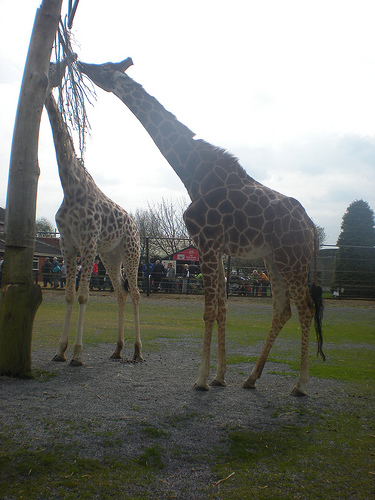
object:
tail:
[310, 222, 326, 365]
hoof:
[51, 352, 66, 363]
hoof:
[61, 357, 86, 366]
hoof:
[109, 349, 121, 358]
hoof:
[131, 351, 144, 361]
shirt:
[258, 273, 268, 281]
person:
[257, 267, 268, 294]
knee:
[76, 294, 86, 304]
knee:
[65, 292, 73, 304]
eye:
[101, 64, 108, 71]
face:
[77, 59, 124, 91]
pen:
[0, 290, 355, 498]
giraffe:
[78, 59, 328, 389]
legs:
[195, 254, 217, 394]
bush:
[333, 199, 373, 296]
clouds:
[190, 9, 360, 80]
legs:
[274, 259, 321, 397]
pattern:
[86, 199, 106, 229]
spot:
[200, 250, 217, 265]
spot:
[204, 272, 210, 289]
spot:
[207, 287, 217, 295]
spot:
[271, 244, 290, 268]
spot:
[292, 259, 303, 273]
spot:
[230, 205, 249, 233]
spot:
[201, 222, 226, 241]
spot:
[185, 197, 208, 226]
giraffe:
[75, 53, 337, 407]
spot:
[304, 227, 316, 244]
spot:
[220, 213, 232, 230]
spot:
[243, 224, 259, 241]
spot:
[247, 209, 265, 232]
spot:
[227, 188, 247, 209]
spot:
[284, 267, 294, 279]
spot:
[295, 284, 305, 301]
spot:
[247, 192, 260, 204]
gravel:
[21, 393, 56, 422]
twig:
[210, 464, 237, 488]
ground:
[23, 404, 353, 488]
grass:
[132, 416, 176, 442]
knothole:
[29, 279, 46, 316]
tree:
[2, 0, 77, 382]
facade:
[157, 243, 202, 265]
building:
[152, 245, 207, 300]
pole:
[144, 234, 151, 297]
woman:
[58, 260, 65, 290]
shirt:
[49, 266, 61, 276]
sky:
[272, 2, 361, 109]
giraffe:
[34, 50, 144, 370]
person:
[193, 267, 203, 292]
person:
[180, 261, 192, 295]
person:
[151, 259, 165, 290]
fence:
[30, 270, 338, 297]